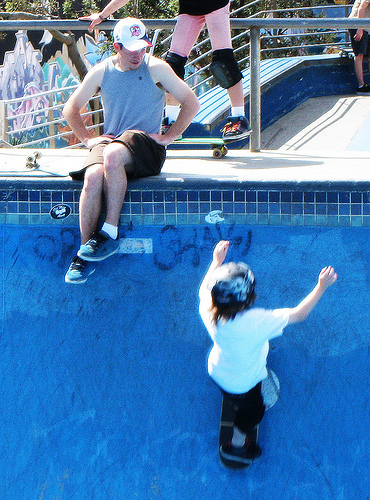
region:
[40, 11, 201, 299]
A man wearing a white hat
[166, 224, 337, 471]
A boy riding a skateboard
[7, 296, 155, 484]
A blue swimming pool wall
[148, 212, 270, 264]
Black graffiti writing on a blue wall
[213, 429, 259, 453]
A boy's black shoe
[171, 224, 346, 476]
A boy wearing a white shirt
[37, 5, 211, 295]
A man wearing shorts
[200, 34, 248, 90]
A black knee pad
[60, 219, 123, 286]
A man's blue shoes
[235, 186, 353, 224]
Blue tile on a swimming pool wall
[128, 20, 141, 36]
a red logo on a hat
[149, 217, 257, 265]
grafitti on a wall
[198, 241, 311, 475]
a person performing a stunt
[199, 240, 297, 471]
a person wearing a white shirt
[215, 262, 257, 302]
a helmet on a head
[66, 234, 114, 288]
blue sneaker with black laces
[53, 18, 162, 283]
a guy sitting on the edge of an empty pool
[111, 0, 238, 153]
a person wearing black knee pads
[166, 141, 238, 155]
a green skateboard with yellow wheels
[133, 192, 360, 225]
blue tiles in the pool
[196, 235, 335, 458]
A person on a skateboard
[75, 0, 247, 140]
A person on a skateboard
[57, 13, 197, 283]
A person sitting down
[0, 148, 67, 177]
A skateboard on the ground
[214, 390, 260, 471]
A skateboard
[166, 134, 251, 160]
A skateboard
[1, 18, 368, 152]
some metal rails atop a pool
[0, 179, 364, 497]
an empty pool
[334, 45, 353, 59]
A skateboard on a ledge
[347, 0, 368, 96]
A man in a brown shirt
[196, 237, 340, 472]
Skateboarder rolls up the side of trough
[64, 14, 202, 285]
Teenager looks on with interest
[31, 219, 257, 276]
Undecipherable graffiti adorns the side of the trough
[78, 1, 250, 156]
A female skateboarder rolls by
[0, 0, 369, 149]
Other parts of skatepark are visible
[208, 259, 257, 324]
Skateboarder wear helmet to prevent injuries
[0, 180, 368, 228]
Tile border of skate trough tells history as a pool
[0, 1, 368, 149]
Plethora of railing indicates safety conciousness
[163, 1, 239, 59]
Pink leggings suggest skateboarder is female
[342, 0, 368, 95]
What appears to be adult about to sit down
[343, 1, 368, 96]
a person leaning over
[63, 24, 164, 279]
a person wearing brown shorts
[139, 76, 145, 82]
a tiny symbol on a gray t-shirt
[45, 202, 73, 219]
a sticker on the pool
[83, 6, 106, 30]
a hand resting on rail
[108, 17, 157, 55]
a hat on a head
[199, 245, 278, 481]
a person on a black skateboard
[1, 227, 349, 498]
a blue wall in the pool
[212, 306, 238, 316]
dark brown hair on a head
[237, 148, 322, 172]
a shadow on the ground